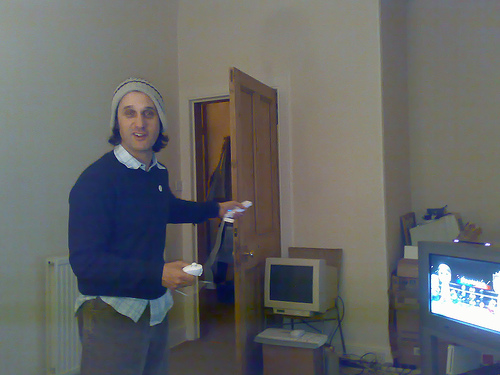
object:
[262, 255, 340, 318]
monitor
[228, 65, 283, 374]
door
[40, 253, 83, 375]
radiator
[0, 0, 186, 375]
wall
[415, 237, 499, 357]
television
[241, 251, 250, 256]
doorknob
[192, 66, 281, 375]
carpeting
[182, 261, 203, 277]
wii joystick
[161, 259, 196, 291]
hand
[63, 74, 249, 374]
man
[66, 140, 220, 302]
shirt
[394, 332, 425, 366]
boxes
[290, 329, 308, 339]
mouse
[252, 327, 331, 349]
keyboard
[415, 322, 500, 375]
tv stand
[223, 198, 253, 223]
game controller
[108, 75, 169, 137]
hat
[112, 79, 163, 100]
stripe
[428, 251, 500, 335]
game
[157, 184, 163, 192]
emblem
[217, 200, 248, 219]
left hand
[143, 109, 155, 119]
left eye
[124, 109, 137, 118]
right eye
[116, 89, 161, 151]
face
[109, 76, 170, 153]
head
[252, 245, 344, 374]
chair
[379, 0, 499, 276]
wall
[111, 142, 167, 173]
shirt collar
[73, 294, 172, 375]
pants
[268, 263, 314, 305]
screen